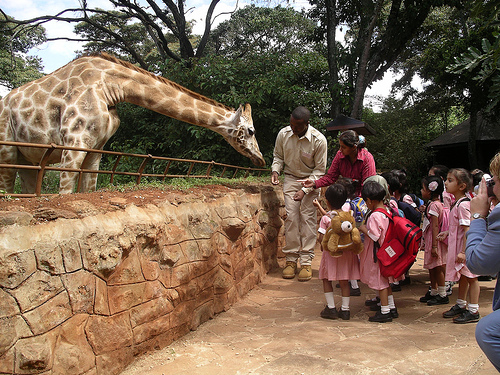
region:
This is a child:
[360, 178, 410, 335]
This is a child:
[315, 180, 360, 331]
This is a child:
[415, 173, 455, 301]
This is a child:
[441, 163, 481, 332]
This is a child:
[468, 165, 490, 320]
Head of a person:
[280, 102, 315, 156]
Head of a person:
[330, 123, 372, 158]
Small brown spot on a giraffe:
[43, 96, 70, 129]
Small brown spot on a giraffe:
[62, 71, 87, 94]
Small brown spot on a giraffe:
[210, 100, 236, 130]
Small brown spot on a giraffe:
[190, 93, 210, 116]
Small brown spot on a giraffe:
[178, 85, 203, 114]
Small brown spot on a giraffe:
[135, 70, 158, 92]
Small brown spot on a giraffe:
[83, 42, 123, 77]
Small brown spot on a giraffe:
[78, 67, 100, 89]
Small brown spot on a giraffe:
[18, 64, 58, 126]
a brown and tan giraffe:
[0, 53, 269, 197]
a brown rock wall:
[1, 182, 278, 373]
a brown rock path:
[125, 247, 499, 372]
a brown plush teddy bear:
[324, 212, 362, 257]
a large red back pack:
[366, 201, 423, 282]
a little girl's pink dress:
[316, 210, 360, 283]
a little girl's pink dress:
[359, 209, 409, 290]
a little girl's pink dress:
[423, 197, 448, 268]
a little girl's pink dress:
[443, 199, 482, 281]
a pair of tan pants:
[278, 172, 320, 266]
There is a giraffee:
[13, 53, 272, 186]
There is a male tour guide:
[261, 96, 320, 296]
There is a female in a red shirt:
[303, 135, 385, 182]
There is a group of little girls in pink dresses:
[326, 166, 499, 305]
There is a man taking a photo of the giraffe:
[465, 148, 497, 365]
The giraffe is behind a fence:
[3, 48, 267, 343]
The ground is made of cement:
[122, 273, 452, 372]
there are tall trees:
[306, 0, 441, 144]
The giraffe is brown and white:
[7, 45, 267, 191]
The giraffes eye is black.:
[244, 125, 258, 138]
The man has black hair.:
[286, 106, 313, 138]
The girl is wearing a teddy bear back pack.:
[317, 210, 365, 255]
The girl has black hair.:
[322, 181, 349, 212]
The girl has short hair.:
[318, 184, 353, 210]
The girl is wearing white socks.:
[321, 287, 352, 312]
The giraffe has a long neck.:
[112, 55, 226, 137]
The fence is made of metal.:
[31, 144, 115, 191]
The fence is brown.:
[29, 143, 122, 187]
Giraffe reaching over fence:
[1, 50, 267, 197]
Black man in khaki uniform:
[270, 103, 327, 280]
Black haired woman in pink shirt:
[300, 128, 377, 190]